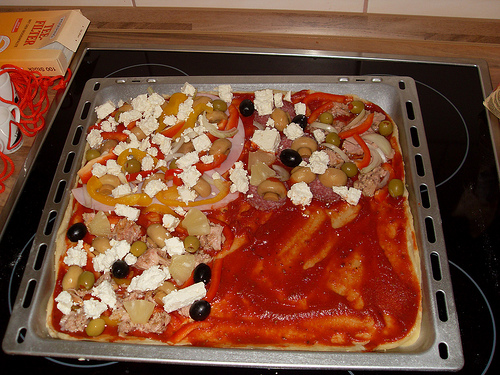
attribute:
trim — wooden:
[1, 5, 499, 90]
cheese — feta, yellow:
[83, 80, 208, 193]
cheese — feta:
[158, 269, 213, 322]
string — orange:
[0, 62, 71, 197]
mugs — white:
[0, 103, 26, 154]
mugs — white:
[0, 68, 21, 106]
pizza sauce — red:
[173, 190, 421, 348]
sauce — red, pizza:
[230, 214, 426, 344]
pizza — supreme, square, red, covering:
[41, 82, 428, 356]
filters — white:
[40, 7, 82, 67]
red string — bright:
[0, 63, 77, 205]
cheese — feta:
[84, 242, 141, 294]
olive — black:
[178, 298, 216, 323]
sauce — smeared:
[47, 89, 419, 349]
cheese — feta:
[230, 123, 297, 161]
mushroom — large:
[253, 179, 303, 210]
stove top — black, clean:
[448, 122, 499, 303]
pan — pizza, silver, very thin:
[3, 71, 465, 373]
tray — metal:
[8, 73, 462, 367]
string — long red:
[4, 62, 81, 137]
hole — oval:
[432, 287, 449, 327]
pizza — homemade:
[62, 79, 440, 349]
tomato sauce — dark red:
[233, 208, 420, 343]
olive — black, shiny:
[189, 299, 210, 321]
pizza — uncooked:
[88, 89, 444, 364]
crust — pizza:
[222, 208, 423, 345]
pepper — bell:
[85, 177, 148, 209]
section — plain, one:
[217, 199, 423, 356]